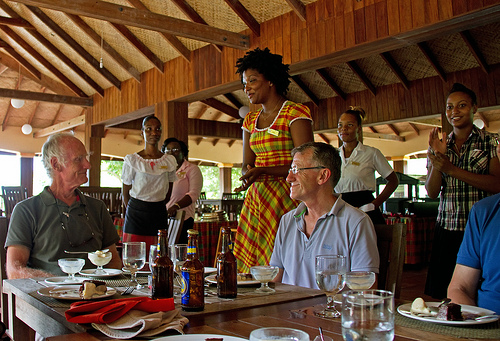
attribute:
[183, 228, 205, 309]
bottle — brown, glass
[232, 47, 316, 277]
waitress — colorful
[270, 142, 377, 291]
man — sitting, smiling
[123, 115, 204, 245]
people — standing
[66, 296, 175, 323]
napkin — red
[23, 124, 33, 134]
light — off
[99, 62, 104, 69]
light — hanging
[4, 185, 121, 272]
shirt — gray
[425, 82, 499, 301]
woman — clapping, smiling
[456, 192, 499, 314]
shirt — blue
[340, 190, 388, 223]
apron — black